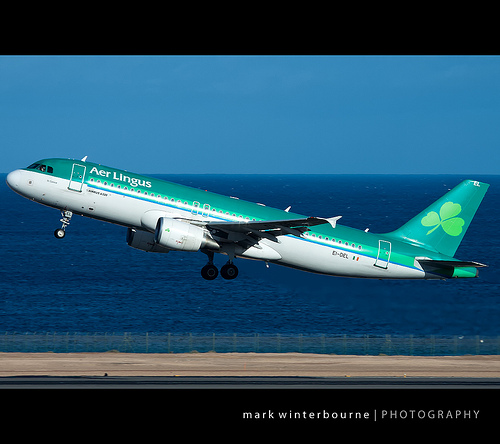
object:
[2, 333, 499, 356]
fence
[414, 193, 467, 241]
shamrock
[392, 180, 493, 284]
tail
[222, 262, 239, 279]
wheel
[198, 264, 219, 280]
wheel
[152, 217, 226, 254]
engine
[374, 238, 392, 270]
door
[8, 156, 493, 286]
plane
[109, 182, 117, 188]
window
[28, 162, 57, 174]
window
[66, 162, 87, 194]
door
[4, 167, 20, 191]
nose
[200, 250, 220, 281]
landing gear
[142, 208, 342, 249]
wing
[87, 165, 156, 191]
letters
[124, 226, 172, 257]
engine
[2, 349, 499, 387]
runway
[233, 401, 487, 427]
watermark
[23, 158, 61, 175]
cockpit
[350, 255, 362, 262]
logo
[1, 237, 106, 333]
water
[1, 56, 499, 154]
sky